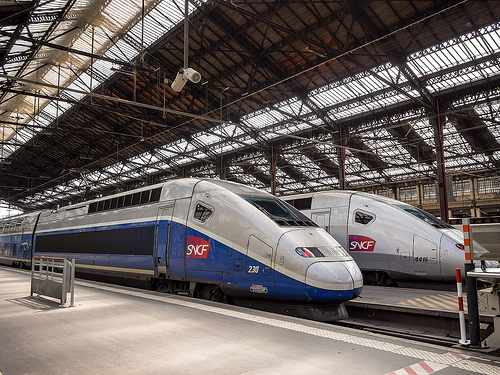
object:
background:
[114, 0, 499, 88]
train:
[0, 174, 367, 322]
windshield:
[240, 193, 320, 232]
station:
[0, 1, 498, 374]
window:
[148, 186, 162, 204]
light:
[180, 66, 206, 85]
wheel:
[190, 277, 222, 302]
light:
[293, 243, 351, 260]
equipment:
[26, 251, 81, 308]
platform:
[0, 264, 499, 375]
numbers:
[245, 262, 252, 274]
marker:
[451, 263, 472, 350]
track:
[331, 298, 499, 361]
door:
[151, 198, 174, 280]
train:
[273, 186, 500, 290]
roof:
[0, 0, 500, 215]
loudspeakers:
[170, 73, 188, 91]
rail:
[458, 213, 483, 352]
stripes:
[455, 268, 463, 314]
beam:
[0, 73, 499, 187]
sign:
[182, 235, 213, 262]